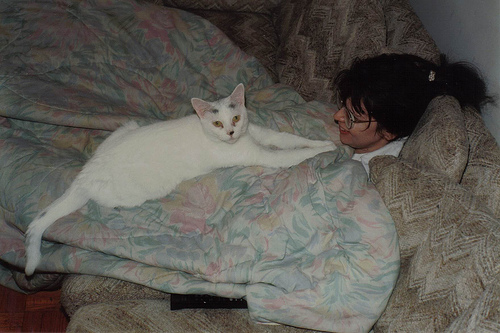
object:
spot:
[205, 104, 221, 116]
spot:
[222, 100, 240, 108]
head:
[186, 81, 250, 145]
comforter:
[0, 0, 402, 333]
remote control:
[167, 294, 248, 310]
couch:
[59, 139, 499, 333]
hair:
[328, 51, 498, 134]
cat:
[21, 77, 340, 278]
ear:
[226, 79, 247, 109]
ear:
[189, 95, 210, 118]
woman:
[325, 50, 488, 166]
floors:
[0, 289, 70, 333]